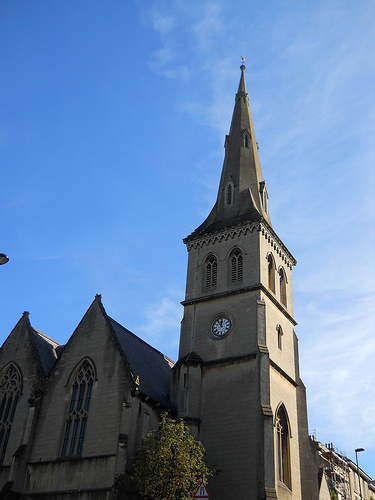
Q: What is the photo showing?
A: It is showing a church.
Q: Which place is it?
A: It is a church.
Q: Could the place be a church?
A: Yes, it is a church.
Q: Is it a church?
A: Yes, it is a church.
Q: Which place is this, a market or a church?
A: It is a church.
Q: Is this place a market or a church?
A: It is a church.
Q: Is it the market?
A: No, it is the church.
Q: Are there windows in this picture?
A: Yes, there are windows.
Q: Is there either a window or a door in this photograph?
A: Yes, there are windows.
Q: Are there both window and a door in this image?
A: No, there are windows but no doors.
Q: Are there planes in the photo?
A: No, there are no planes.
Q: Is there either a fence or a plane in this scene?
A: No, there are no airplanes or fences.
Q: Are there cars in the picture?
A: No, there are no cars.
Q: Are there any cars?
A: No, there are no cars.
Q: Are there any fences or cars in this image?
A: No, there are no cars or fences.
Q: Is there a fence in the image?
A: No, there are no fences.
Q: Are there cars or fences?
A: No, there are no fences or cars.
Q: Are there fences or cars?
A: No, there are no fences or cars.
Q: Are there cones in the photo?
A: No, there are no cones.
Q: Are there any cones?
A: No, there are no cones.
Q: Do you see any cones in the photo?
A: No, there are no cones.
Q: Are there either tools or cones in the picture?
A: No, there are no cones or tools.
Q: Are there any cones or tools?
A: No, there are no cones or tools.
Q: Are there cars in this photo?
A: No, there are no cars.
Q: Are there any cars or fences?
A: No, there are no cars or fences.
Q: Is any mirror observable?
A: No, there are no mirrors.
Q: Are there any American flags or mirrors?
A: No, there are no mirrors or American flags.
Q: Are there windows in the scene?
A: Yes, there is a window.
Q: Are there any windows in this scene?
A: Yes, there is a window.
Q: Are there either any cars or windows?
A: Yes, there is a window.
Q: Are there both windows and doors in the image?
A: No, there is a window but no doors.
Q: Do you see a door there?
A: No, there are no doors.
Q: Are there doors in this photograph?
A: No, there are no doors.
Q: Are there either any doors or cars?
A: No, there are no doors or cars.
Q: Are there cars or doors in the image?
A: No, there are no doors or cars.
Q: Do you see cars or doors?
A: No, there are no doors or cars.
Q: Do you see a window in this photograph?
A: Yes, there is a window.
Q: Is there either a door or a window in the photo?
A: Yes, there is a window.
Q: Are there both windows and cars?
A: No, there is a window but no cars.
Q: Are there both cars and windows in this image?
A: No, there is a window but no cars.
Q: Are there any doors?
A: No, there are no doors.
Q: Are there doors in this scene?
A: No, there are no doors.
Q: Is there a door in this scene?
A: No, there are no doors.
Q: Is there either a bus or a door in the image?
A: No, there are no doors or buses.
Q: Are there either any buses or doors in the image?
A: No, there are no doors or buses.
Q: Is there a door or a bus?
A: No, there are no doors or buses.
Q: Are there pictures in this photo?
A: No, there are no pictures.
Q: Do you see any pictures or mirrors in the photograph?
A: No, there are no pictures or mirrors.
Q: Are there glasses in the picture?
A: No, there are no glasses.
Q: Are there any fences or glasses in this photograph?
A: No, there are no glasses or fences.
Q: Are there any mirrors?
A: No, there are no mirrors.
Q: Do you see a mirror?
A: No, there are no mirrors.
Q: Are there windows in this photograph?
A: Yes, there are windows.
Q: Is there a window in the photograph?
A: Yes, there are windows.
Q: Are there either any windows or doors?
A: Yes, there are windows.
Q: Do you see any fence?
A: No, there are no fences.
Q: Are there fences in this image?
A: No, there are no fences.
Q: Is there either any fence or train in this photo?
A: No, there are no fences or trains.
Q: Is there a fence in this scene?
A: No, there are no fences.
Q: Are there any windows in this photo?
A: Yes, there is a window.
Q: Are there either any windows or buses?
A: Yes, there is a window.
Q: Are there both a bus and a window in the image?
A: No, there is a window but no buses.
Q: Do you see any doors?
A: No, there are no doors.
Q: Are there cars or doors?
A: No, there are no doors or cars.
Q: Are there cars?
A: No, there are no cars.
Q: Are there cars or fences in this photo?
A: No, there are no cars or fences.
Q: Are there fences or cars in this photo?
A: No, there are no cars or fences.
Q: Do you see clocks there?
A: Yes, there is a clock.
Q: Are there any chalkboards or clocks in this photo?
A: Yes, there is a clock.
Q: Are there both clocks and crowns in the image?
A: No, there is a clock but no crowns.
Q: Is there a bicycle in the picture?
A: No, there are no bicycles.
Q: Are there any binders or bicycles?
A: No, there are no bicycles or binders.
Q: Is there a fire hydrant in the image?
A: No, there are no fire hydrants.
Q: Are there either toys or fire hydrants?
A: No, there are no fire hydrants or toys.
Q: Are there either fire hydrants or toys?
A: No, there are no fire hydrants or toys.